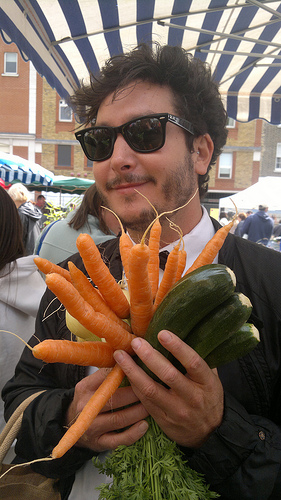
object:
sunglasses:
[73, 112, 204, 163]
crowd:
[125, 117, 163, 151]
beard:
[130, 148, 192, 232]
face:
[88, 73, 214, 226]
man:
[1, 40, 280, 495]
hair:
[71, 41, 230, 195]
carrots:
[28, 188, 235, 459]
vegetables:
[33, 214, 258, 499]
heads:
[95, 417, 224, 499]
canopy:
[1, 3, 280, 130]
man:
[232, 201, 275, 246]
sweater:
[234, 212, 277, 235]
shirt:
[127, 207, 219, 268]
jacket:
[1, 225, 277, 499]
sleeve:
[179, 391, 280, 497]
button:
[255, 427, 268, 443]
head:
[67, 42, 229, 225]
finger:
[153, 327, 211, 382]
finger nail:
[155, 327, 176, 346]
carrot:
[186, 212, 248, 263]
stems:
[128, 183, 166, 218]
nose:
[110, 134, 137, 175]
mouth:
[105, 180, 155, 192]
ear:
[190, 130, 215, 179]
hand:
[111, 328, 227, 452]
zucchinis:
[145, 261, 263, 370]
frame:
[25, 0, 280, 86]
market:
[0, 150, 279, 250]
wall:
[38, 77, 258, 191]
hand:
[65, 362, 151, 456]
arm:
[3, 275, 146, 475]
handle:
[1, 390, 48, 469]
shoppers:
[0, 180, 53, 260]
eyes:
[87, 130, 161, 148]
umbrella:
[1, 151, 57, 189]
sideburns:
[180, 131, 198, 181]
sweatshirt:
[1, 256, 49, 382]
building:
[1, 34, 263, 189]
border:
[25, 62, 38, 160]